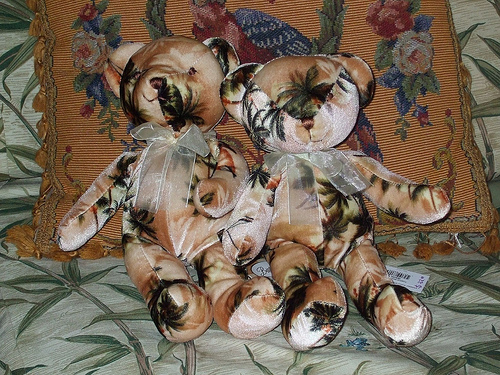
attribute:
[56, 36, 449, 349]
bears — pair, sitting, brown, black, stuffed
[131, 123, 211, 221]
bow — white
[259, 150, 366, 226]
bow — white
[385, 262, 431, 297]
tag — white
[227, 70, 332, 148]
print — palm tree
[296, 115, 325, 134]
nose — brown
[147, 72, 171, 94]
nose — brown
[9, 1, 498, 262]
pillow — yellow, brown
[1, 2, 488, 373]
blanket — green, tan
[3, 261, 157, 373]
print —   bamboo, of comforter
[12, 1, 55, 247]
tassles — in row, brown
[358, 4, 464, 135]
pattern — floral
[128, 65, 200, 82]
eyes — brown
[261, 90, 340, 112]
eyes — brown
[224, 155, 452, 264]
arms — open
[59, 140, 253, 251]
arms — open